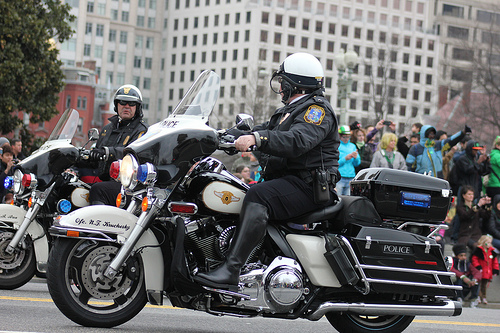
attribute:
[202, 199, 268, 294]
boot — black 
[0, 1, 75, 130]
leaves — green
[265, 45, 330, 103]
helmet — black , white 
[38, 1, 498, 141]
building — tall 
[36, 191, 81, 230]
blue light — blue 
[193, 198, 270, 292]
boot — tall , black , leather 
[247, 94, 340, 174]
jacket — black 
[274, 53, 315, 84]
helmet — white 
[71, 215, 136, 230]
script — black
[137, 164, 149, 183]
light — blue 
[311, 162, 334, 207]
walkietalkie — black 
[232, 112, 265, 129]
mirror — chrome  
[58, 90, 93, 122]
wall — red